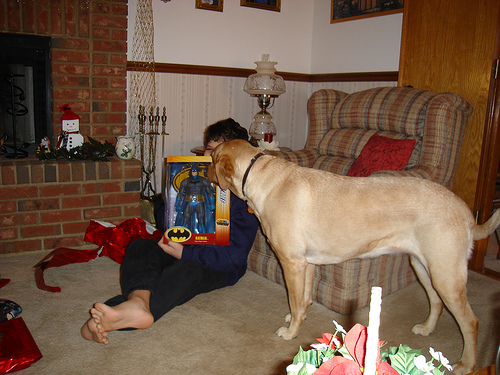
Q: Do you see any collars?
A: Yes, there is a collar.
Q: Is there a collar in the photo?
A: Yes, there is a collar.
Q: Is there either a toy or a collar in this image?
A: Yes, there is a collar.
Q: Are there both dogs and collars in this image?
A: Yes, there are both a collar and a dog.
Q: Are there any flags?
A: No, there are no flags.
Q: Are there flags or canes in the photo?
A: No, there are no flags or canes.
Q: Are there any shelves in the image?
A: No, there are no shelves.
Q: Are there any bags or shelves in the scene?
A: No, there are no shelves or bags.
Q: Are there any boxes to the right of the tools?
A: Yes, there is a box to the right of the tools.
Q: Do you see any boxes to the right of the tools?
A: Yes, there is a box to the right of the tools.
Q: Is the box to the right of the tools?
A: Yes, the box is to the right of the tools.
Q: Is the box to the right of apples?
A: No, the box is to the right of the tools.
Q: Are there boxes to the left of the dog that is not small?
A: Yes, there is a box to the left of the dog.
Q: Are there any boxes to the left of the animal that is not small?
A: Yes, there is a box to the left of the dog.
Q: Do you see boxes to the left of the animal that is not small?
A: Yes, there is a box to the left of the dog.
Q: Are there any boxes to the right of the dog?
A: No, the box is to the left of the dog.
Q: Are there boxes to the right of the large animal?
A: No, the box is to the left of the dog.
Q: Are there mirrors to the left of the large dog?
A: No, there is a box to the left of the dog.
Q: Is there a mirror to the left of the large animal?
A: No, there is a box to the left of the dog.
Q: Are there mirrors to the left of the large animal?
A: No, there is a box to the left of the dog.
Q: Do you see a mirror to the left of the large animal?
A: No, there is a box to the left of the dog.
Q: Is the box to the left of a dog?
A: Yes, the box is to the left of a dog.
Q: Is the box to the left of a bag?
A: No, the box is to the left of a dog.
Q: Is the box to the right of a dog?
A: No, the box is to the left of a dog.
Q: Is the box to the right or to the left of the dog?
A: The box is to the left of the dog.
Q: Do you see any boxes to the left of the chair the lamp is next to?
A: Yes, there is a box to the left of the chair.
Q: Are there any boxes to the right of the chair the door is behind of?
A: No, the box is to the left of the chair.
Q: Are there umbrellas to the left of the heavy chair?
A: No, there is a box to the left of the chair.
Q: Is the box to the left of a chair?
A: Yes, the box is to the left of a chair.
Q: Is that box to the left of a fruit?
A: No, the box is to the left of a chair.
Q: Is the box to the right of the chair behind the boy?
A: No, the box is to the left of the chair.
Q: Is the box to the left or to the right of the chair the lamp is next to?
A: The box is to the left of the chair.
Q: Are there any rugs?
A: No, there are no rugs.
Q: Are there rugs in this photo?
A: No, there are no rugs.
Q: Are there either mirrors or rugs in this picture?
A: No, there are no rugs or mirrors.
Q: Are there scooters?
A: No, there are no scooters.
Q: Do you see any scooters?
A: No, there are no scooters.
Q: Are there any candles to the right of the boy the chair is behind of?
A: Yes, there is a candle to the right of the boy.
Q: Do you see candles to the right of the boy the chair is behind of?
A: Yes, there is a candle to the right of the boy.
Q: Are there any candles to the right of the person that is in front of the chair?
A: Yes, there is a candle to the right of the boy.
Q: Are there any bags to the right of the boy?
A: No, there is a candle to the right of the boy.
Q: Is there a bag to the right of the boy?
A: No, there is a candle to the right of the boy.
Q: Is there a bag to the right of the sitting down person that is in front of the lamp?
A: No, there is a candle to the right of the boy.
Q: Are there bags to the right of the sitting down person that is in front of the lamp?
A: No, there is a candle to the right of the boy.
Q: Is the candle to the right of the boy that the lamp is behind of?
A: Yes, the candle is to the right of the boy.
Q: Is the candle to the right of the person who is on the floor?
A: Yes, the candle is to the right of the boy.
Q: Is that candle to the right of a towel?
A: No, the candle is to the right of the boy.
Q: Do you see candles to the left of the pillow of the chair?
A: Yes, there is a candle to the left of the pillow.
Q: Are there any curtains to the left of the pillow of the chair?
A: No, there is a candle to the left of the pillow.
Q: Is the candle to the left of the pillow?
A: Yes, the candle is to the left of the pillow.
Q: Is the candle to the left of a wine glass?
A: No, the candle is to the left of the pillow.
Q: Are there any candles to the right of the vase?
A: Yes, there is a candle to the right of the vase.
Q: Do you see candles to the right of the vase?
A: Yes, there is a candle to the right of the vase.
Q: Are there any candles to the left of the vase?
A: No, the candle is to the right of the vase.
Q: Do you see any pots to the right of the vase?
A: No, there is a candle to the right of the vase.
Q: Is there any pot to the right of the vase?
A: No, there is a candle to the right of the vase.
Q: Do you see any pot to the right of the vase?
A: No, there is a candle to the right of the vase.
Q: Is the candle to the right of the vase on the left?
A: Yes, the candle is to the right of the vase.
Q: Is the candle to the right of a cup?
A: No, the candle is to the right of the vase.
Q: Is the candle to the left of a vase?
A: No, the candle is to the right of a vase.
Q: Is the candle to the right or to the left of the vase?
A: The candle is to the right of the vase.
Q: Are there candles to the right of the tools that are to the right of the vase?
A: Yes, there is a candle to the right of the tools.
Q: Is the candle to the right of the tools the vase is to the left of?
A: Yes, the candle is to the right of the tools.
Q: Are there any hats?
A: Yes, there is a hat.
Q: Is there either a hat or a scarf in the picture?
A: Yes, there is a hat.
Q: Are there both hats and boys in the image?
A: Yes, there are both a hat and a boy.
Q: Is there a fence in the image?
A: No, there are no fences.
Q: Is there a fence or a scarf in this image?
A: No, there are no fences or scarves.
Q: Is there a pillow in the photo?
A: Yes, there is a pillow.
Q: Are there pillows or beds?
A: Yes, there is a pillow.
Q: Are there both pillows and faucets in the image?
A: No, there is a pillow but no faucets.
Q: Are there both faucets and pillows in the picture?
A: No, there is a pillow but no faucets.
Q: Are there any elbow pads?
A: No, there are no elbow pads.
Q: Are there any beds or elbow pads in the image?
A: No, there are no elbow pads or beds.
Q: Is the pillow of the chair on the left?
A: No, the pillow is on the right of the image.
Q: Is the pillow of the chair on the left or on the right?
A: The pillow is on the right of the image.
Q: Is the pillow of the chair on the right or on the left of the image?
A: The pillow is on the right of the image.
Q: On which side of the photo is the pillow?
A: The pillow is on the right of the image.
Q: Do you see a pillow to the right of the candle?
A: Yes, there is a pillow to the right of the candle.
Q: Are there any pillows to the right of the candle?
A: Yes, there is a pillow to the right of the candle.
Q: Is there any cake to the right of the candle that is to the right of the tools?
A: No, there is a pillow to the right of the candle.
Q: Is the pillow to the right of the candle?
A: Yes, the pillow is to the right of the candle.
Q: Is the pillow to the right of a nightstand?
A: No, the pillow is to the right of the candle.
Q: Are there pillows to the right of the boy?
A: Yes, there is a pillow to the right of the boy.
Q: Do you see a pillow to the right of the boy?
A: Yes, there is a pillow to the right of the boy.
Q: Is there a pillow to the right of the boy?
A: Yes, there is a pillow to the right of the boy.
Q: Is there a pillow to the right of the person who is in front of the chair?
A: Yes, there is a pillow to the right of the boy.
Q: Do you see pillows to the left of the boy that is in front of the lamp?
A: No, the pillow is to the right of the boy.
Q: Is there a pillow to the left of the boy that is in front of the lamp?
A: No, the pillow is to the right of the boy.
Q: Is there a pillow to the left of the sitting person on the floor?
A: No, the pillow is to the right of the boy.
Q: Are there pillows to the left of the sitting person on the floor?
A: No, the pillow is to the right of the boy.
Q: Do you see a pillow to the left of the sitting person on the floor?
A: No, the pillow is to the right of the boy.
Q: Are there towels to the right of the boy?
A: No, there is a pillow to the right of the boy.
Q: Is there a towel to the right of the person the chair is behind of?
A: No, there is a pillow to the right of the boy.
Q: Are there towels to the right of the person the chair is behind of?
A: No, there is a pillow to the right of the boy.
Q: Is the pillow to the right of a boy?
A: Yes, the pillow is to the right of a boy.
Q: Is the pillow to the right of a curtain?
A: No, the pillow is to the right of a boy.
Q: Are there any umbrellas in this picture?
A: No, there are no umbrellas.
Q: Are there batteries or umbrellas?
A: No, there are no umbrellas or batteries.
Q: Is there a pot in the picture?
A: No, there are no pots.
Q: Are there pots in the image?
A: No, there are no pots.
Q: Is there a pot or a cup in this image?
A: No, there are no pots or cups.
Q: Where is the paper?
A: The paper is on the floor.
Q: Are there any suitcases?
A: No, there are no suitcases.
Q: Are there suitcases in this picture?
A: No, there are no suitcases.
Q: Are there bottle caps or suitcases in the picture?
A: No, there are no suitcases or bottle caps.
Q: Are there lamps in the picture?
A: Yes, there is a lamp.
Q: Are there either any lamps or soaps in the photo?
A: Yes, there is a lamp.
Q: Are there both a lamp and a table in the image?
A: No, there is a lamp but no tables.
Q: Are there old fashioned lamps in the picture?
A: Yes, there is an old fashioned lamp.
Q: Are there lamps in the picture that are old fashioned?
A: Yes, there is a lamp that is old fashioned.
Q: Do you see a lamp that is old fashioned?
A: Yes, there is a lamp that is old fashioned.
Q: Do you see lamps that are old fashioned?
A: Yes, there is a lamp that is old fashioned.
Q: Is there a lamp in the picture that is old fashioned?
A: Yes, there is a lamp that is old fashioned.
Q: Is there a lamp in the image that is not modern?
A: Yes, there is a old fashioned lamp.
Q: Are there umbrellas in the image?
A: No, there are no umbrellas.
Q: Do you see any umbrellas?
A: No, there are no umbrellas.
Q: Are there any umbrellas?
A: No, there are no umbrellas.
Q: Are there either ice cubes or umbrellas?
A: No, there are no umbrellas or ice cubes.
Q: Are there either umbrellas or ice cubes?
A: No, there are no umbrellas or ice cubes.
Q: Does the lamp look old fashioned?
A: Yes, the lamp is old fashioned.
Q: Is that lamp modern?
A: No, the lamp is old fashioned.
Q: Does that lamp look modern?
A: No, the lamp is old fashioned.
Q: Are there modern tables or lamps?
A: No, there is a lamp but it is old fashioned.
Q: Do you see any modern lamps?
A: No, there is a lamp but it is old fashioned.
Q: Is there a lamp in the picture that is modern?
A: No, there is a lamp but it is old fashioned.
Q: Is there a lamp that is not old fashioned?
A: No, there is a lamp but it is old fashioned.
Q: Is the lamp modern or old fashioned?
A: The lamp is old fashioned.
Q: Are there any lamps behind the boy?
A: Yes, there is a lamp behind the boy.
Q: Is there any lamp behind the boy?
A: Yes, there is a lamp behind the boy.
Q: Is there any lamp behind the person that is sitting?
A: Yes, there is a lamp behind the boy.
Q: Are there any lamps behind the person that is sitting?
A: Yes, there is a lamp behind the boy.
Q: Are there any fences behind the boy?
A: No, there is a lamp behind the boy.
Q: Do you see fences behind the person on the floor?
A: No, there is a lamp behind the boy.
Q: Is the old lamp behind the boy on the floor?
A: Yes, the lamp is behind the boy.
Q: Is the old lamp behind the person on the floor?
A: Yes, the lamp is behind the boy.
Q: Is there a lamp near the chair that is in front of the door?
A: Yes, there is a lamp near the chair.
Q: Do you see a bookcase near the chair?
A: No, there is a lamp near the chair.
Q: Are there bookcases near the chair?
A: No, there is a lamp near the chair.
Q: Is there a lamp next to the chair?
A: Yes, there is a lamp next to the chair.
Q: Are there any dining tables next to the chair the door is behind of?
A: No, there is a lamp next to the chair.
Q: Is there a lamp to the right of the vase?
A: Yes, there is a lamp to the right of the vase.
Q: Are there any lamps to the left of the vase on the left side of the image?
A: No, the lamp is to the right of the vase.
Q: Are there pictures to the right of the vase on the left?
A: No, there is a lamp to the right of the vase.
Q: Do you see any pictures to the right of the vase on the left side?
A: No, there is a lamp to the right of the vase.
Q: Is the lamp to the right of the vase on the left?
A: Yes, the lamp is to the right of the vase.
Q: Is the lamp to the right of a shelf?
A: No, the lamp is to the right of the vase.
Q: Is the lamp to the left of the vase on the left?
A: No, the lamp is to the right of the vase.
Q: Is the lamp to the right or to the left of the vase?
A: The lamp is to the right of the vase.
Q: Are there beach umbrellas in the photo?
A: No, there are no beach umbrellas.